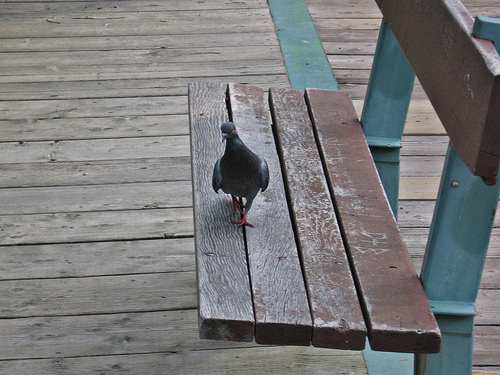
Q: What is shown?
A: A bird.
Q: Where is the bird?
A: On a bench.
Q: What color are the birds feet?
A: Orange.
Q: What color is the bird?
A: Grey.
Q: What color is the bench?
A: Brown and blue.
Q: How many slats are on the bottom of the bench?
A: 4.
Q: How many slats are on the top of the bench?
A: 1.